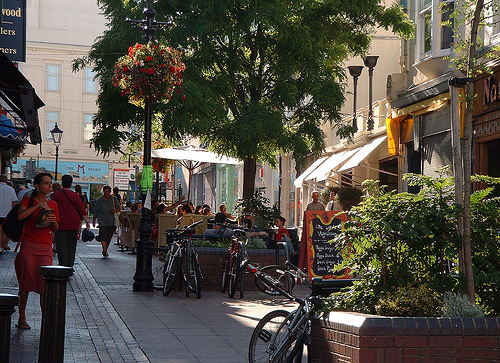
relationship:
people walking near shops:
[0, 160, 345, 332] [166, 2, 496, 273]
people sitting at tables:
[120, 198, 290, 245] [105, 203, 249, 238]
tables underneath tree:
[138, 82, 298, 270] [70, 0, 418, 220]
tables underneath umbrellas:
[138, 82, 298, 270] [141, 134, 248, 175]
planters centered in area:
[162, 215, 289, 311] [1, 208, 484, 358]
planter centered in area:
[305, 298, 483, 361] [1, 208, 484, 358]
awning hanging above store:
[290, 154, 327, 188] [303, 123, 410, 232]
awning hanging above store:
[302, 149, 345, 187] [303, 123, 410, 232]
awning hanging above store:
[314, 146, 357, 183] [303, 123, 410, 232]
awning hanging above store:
[336, 133, 386, 173] [303, 123, 410, 232]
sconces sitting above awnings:
[361, 54, 379, 134] [292, 132, 392, 189]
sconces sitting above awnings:
[346, 63, 364, 134] [292, 132, 392, 189]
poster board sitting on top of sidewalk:
[306, 210, 341, 276] [155, 297, 297, 310]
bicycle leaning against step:
[246, 284, 338, 360] [302, 301, 482, 360]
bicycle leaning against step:
[216, 222, 253, 294] [168, 240, 294, 293]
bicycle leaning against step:
[237, 252, 302, 303] [168, 240, 294, 293]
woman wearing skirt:
[13, 172, 60, 329] [12, 247, 45, 303]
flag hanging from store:
[382, 112, 413, 159] [394, 90, 471, 235]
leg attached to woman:
[39, 285, 46, 324] [13, 172, 60, 329]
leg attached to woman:
[14, 255, 32, 331] [13, 172, 60, 329]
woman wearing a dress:
[15, 170, 63, 314] [13, 201, 60, 312]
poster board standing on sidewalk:
[305, 210, 356, 283] [2, 222, 325, 361]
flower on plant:
[133, 41, 142, 50] [108, 39, 186, 112]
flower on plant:
[145, 67, 154, 76] [108, 39, 186, 112]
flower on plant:
[145, 53, 152, 63] [108, 39, 186, 112]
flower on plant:
[151, 44, 158, 50] [108, 39, 186, 112]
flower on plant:
[175, 65, 181, 74] [108, 39, 186, 112]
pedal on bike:
[255, 327, 277, 343] [242, 258, 324, 360]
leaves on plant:
[324, 177, 426, 254] [326, 168, 456, 295]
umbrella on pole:
[132, 144, 244, 166] [176, 159, 208, 205]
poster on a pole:
[140, 165, 154, 194] [130, 55, 159, 294]